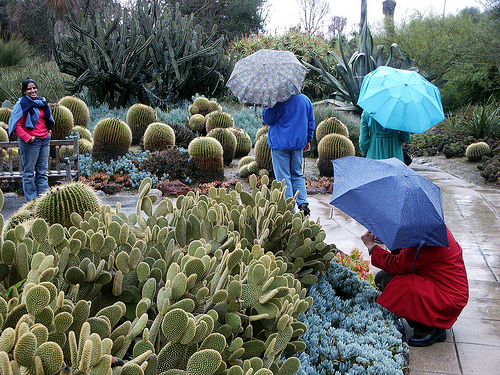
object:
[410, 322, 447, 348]
shoe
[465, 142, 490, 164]
cactus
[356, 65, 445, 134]
light-blue umbrella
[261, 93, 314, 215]
person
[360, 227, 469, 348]
person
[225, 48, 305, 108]
umbrella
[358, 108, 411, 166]
person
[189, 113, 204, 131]
small cactus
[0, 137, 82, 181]
bench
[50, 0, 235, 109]
cactus branches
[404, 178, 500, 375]
ground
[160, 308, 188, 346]
cactus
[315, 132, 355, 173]
cactus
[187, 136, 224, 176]
cactus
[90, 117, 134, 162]
cactus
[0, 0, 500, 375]
garden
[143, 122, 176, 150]
cactus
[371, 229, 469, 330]
coat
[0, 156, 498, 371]
sidewalk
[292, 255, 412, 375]
blue flowers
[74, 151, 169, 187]
blue flowers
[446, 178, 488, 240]
pathway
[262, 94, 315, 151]
jacket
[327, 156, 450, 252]
blue umbrella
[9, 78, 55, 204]
woman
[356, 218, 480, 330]
red coat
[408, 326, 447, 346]
foot